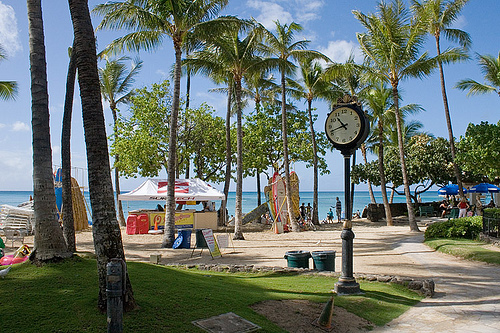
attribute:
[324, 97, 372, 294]
clock — black, gold, large, circular, outdoor, beach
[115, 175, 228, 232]
stand — food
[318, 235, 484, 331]
walkway — sand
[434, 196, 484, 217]
people — talking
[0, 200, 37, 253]
chairs — beach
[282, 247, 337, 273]
trashcan — true, green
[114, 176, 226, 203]
tent — white, red, black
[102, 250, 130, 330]
pump — black, grey, outdoor, water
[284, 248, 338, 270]
cans — green, trash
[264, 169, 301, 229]
boards — colorful, surf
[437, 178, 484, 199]
umbrellas — blue, white, outdoor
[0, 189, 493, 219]
ocean — Beautful, calm, blue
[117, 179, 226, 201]
roof cover — red, white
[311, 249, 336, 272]
trash can — green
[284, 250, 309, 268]
trash can — green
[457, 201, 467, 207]
shirt — red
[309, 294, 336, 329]
cone — dirty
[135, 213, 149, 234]
box — red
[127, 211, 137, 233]
box — red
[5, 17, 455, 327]
park — BEACH, MANY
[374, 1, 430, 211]
tree — PALM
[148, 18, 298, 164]
trees — PALM, MULTIPLE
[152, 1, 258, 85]
trees — PALM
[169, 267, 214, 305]
grass — SHORT, CUT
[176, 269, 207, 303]
grass — CUT, GREEN, SHORT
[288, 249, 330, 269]
cans — 2, GREEN, GARBAGE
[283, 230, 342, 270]
cans — GARBAGE, GREEN, 2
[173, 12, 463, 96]
trees — PALM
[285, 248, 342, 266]
cans — TRASH, GREEN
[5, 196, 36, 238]
furniture — PILE, BEACH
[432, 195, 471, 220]
people — GROUP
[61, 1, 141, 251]
tree — PALM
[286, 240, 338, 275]
cans — GREEN, TRASH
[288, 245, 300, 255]
bags — PLASTIC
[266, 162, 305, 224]
surfboards — GROUP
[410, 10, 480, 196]
tree — PALM, LEANING, TALL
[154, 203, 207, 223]
sign — BOARD, SANDWICH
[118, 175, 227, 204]
tarp — red, white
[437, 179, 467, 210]
umbrella — blue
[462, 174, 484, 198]
umbrella — blue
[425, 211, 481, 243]
bushes — shaped, green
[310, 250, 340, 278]
trashcan — green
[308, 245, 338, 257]
lid — grey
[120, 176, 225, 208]
canopy — red, white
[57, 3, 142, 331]
tree — tall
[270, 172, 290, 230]
surfboard — red, white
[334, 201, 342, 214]
shirt — striped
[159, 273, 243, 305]
grass — green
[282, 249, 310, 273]
trash can — green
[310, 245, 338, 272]
trash can — green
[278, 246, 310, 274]
garbage bin — green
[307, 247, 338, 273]
garbage bin — green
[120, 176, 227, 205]
canopy — white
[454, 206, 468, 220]
pants — white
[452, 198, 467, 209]
shirt — red